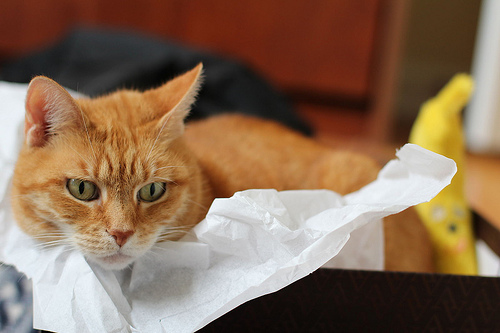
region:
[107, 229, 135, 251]
the nose is pink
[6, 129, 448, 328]
the paper is white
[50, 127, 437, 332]
the paper is crumpled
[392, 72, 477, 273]
the object is yellow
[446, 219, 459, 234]
a black mark on the object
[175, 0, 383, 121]
a brown door behind the cat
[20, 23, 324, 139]
a black cloth behind the cat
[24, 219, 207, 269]
the cat has white whiskers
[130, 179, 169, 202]
the cat has a left ear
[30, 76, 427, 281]
the cat is reddish brown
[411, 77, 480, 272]
yellow banana shaped toy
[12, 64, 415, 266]
front of orange cat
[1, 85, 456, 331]
crumpled paper under cat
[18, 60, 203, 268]
face on cat head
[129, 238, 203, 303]
shadow of head on paper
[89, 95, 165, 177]
orange stripes on head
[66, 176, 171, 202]
green eyes on cat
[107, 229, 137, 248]
pink nose on cat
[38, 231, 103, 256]
whiskers on cat cheeks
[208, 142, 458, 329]
crumpled edge of paper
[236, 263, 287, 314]
edge of a paper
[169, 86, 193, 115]
edge of an ear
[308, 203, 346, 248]
part of a paper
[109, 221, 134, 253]
;part of a nose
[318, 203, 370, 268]
edge of a paper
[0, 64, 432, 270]
Orange and white cat.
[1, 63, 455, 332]
The cat is lying on white tissue paper.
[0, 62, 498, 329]
Cat is lying in a black box top.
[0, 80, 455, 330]
The tissue paper is crinkled.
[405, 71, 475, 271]
Edge of a yellow cloth inside of the lid.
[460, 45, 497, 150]
Bottom edge of a white door.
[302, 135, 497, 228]
The flooring is brown.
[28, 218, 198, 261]
The cat has white whiskers.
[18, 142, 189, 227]
Dark orange stripes on the cat's face.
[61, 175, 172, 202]
Cat has green eyes.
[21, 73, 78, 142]
the right ear is pink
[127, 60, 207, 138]
the left ear is brown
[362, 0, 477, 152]
a wall corner behind the object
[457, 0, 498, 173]
a white object by the corner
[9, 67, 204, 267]
the cat's chin is on the paper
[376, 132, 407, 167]
a small rip in the paper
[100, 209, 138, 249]
the cat has a pink nose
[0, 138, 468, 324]
the paper is crumbled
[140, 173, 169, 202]
the cat has a left eye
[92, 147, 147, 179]
stripes on the cat face